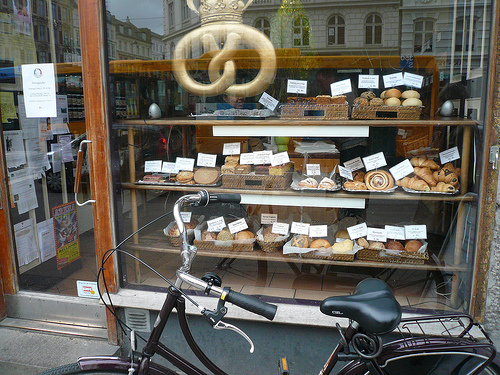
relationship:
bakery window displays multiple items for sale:
[2, 116, 498, 257] [185, 116, 420, 307]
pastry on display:
[308, 236, 332, 250] [404, 142, 472, 216]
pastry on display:
[308, 236, 332, 250] [386, 144, 464, 203]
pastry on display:
[308, 236, 332, 250] [384, 226, 428, 273]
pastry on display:
[308, 236, 332, 250] [386, 219, 435, 255]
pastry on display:
[308, 236, 332, 250] [367, 222, 409, 257]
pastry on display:
[308, 236, 332, 250] [322, 221, 374, 271]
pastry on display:
[314, 234, 328, 260] [297, 211, 333, 272]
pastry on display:
[308, 236, 332, 250] [281, 207, 334, 273]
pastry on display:
[308, 236, 332, 250] [249, 215, 294, 282]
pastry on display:
[308, 236, 332, 250] [231, 214, 261, 254]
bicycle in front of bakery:
[99, 186, 484, 375] [0, 0, 500, 340]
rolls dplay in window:
[351, 156, 387, 194] [205, 144, 446, 285]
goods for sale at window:
[194, 150, 342, 252] [104, 52, 478, 278]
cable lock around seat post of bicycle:
[329, 310, 389, 357] [132, 259, 469, 375]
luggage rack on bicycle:
[352, 315, 485, 375] [136, 252, 497, 375]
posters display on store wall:
[16, 144, 81, 251] [11, 174, 85, 320]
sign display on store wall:
[18, 59, 60, 119] [11, 174, 85, 320]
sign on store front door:
[18, 59, 63, 159] [22, 111, 141, 374]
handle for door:
[71, 132, 92, 219] [0, 0, 108, 333]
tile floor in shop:
[99, 251, 456, 280] [134, 154, 355, 294]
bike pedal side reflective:
[264, 341, 291, 375] [270, 357, 298, 375]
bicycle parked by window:
[34, 189, 500, 375] [133, 187, 416, 235]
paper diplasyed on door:
[20, 60, 57, 120] [1, 1, 105, 328]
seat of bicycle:
[322, 271, 402, 331] [34, 189, 500, 375]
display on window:
[168, 0, 276, 95] [101, 0, 494, 325]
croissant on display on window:
[396, 175, 428, 191] [101, 0, 494, 325]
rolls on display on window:
[364, 166, 395, 195] [101, 0, 494, 325]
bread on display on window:
[193, 165, 220, 184] [101, 0, 494, 325]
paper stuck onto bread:
[364, 150, 389, 171] [364, 169, 395, 191]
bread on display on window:
[382, 87, 402, 99] [101, 0, 494, 325]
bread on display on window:
[320, 179, 340, 189] [101, 0, 494, 325]